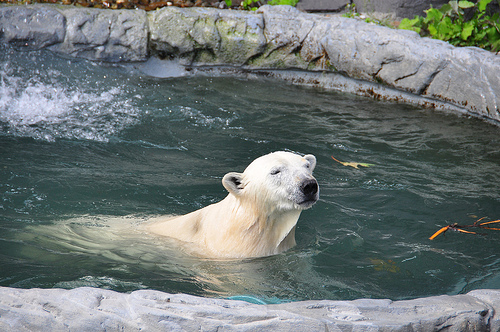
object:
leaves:
[398, 0, 500, 51]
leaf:
[331, 155, 376, 169]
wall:
[294, 2, 440, 37]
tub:
[1, 5, 498, 329]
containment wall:
[0, 4, 500, 127]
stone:
[48, 4, 458, 80]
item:
[429, 216, 499, 240]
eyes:
[270, 170, 280, 175]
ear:
[221, 172, 243, 198]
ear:
[303, 154, 317, 172]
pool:
[5, 2, 499, 332]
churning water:
[0, 62, 138, 141]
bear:
[51, 151, 320, 263]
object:
[223, 294, 267, 305]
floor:
[286, 114, 336, 190]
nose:
[301, 179, 318, 194]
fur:
[151, 203, 267, 261]